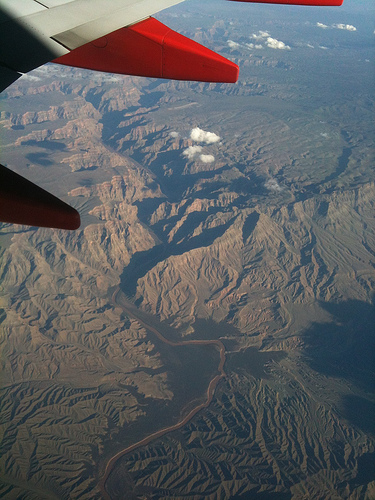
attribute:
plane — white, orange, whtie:
[0, 3, 342, 230]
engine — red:
[60, 19, 239, 85]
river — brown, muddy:
[105, 324, 226, 467]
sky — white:
[0, 1, 374, 499]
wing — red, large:
[2, 4, 191, 92]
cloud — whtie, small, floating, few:
[184, 123, 223, 166]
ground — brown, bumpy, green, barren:
[0, 3, 374, 499]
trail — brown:
[133, 187, 250, 434]